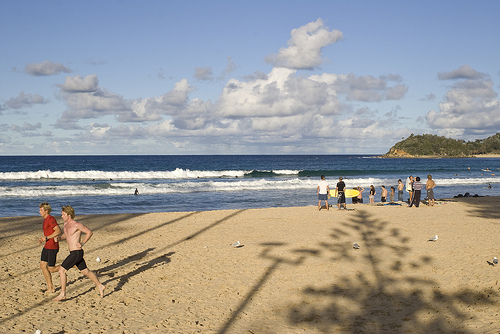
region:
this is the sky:
[70, 8, 231, 54]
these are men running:
[15, 188, 115, 314]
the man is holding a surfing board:
[324, 169, 360, 214]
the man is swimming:
[120, 180, 158, 203]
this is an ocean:
[82, 150, 319, 172]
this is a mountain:
[377, 130, 480, 157]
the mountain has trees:
[391, 129, 473, 155]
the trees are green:
[398, 132, 476, 154]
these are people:
[278, 159, 452, 223]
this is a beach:
[0, 184, 422, 301]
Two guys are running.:
[22, 178, 139, 315]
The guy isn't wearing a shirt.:
[49, 196, 100, 272]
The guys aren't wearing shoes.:
[32, 277, 147, 304]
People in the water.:
[82, 160, 241, 215]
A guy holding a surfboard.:
[321, 185, 378, 200]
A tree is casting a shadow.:
[322, 202, 460, 327]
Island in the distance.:
[381, 122, 498, 158]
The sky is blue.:
[71, 10, 248, 66]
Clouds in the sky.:
[129, 43, 373, 143]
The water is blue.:
[73, 146, 277, 174]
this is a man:
[59, 194, 101, 298]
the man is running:
[57, 199, 103, 304]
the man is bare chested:
[65, 218, 85, 248]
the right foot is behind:
[85, 268, 108, 294]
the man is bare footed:
[56, 277, 112, 302]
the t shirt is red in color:
[42, 218, 52, 251]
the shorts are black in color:
[67, 251, 84, 268]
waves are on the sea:
[11, 162, 237, 182]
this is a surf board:
[346, 188, 357, 197]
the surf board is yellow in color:
[346, 185, 358, 198]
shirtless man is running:
[53, 206, 105, 303]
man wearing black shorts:
[60, 248, 87, 270]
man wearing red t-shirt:
[38, 215, 60, 250]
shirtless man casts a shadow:
[62, 250, 174, 297]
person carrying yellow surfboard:
[329, 177, 358, 209]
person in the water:
[133, 186, 143, 195]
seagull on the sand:
[228, 237, 244, 247]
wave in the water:
[1, 167, 308, 181]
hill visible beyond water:
[366, 132, 499, 159]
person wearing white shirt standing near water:
[314, 180, 331, 209]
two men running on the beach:
[38, 202, 104, 297]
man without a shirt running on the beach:
[58, 204, 105, 301]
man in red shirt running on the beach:
[36, 202, 61, 293]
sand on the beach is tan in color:
[2, 197, 499, 330]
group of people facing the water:
[316, 175, 434, 206]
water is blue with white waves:
[0, 152, 499, 215]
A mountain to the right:
[386, 130, 499, 155]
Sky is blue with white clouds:
[1, 0, 498, 155]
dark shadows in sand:
[0, 197, 499, 329]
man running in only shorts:
[58, 207, 103, 302]